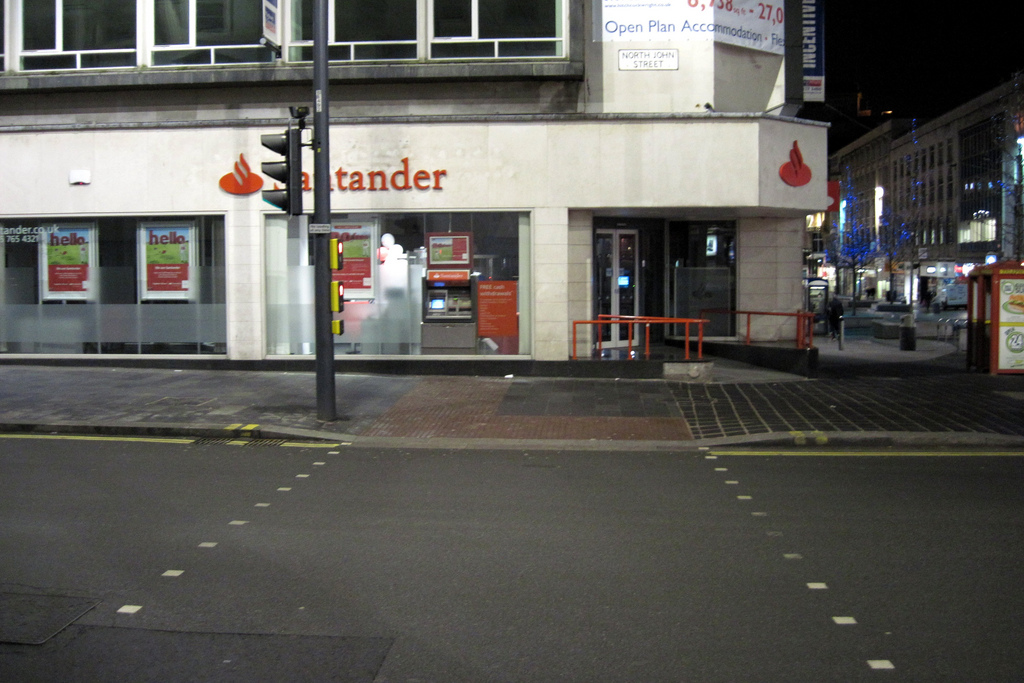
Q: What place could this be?
A: It is a store.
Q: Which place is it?
A: It is a store.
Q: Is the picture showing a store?
A: Yes, it is showing a store.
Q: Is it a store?
A: Yes, it is a store.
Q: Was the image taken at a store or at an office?
A: It was taken at a store.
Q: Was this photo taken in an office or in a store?
A: It was taken at a store.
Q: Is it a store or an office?
A: It is a store.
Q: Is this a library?
A: No, it is a store.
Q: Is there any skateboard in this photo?
A: No, there are no skateboards.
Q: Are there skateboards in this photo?
A: No, there are no skateboards.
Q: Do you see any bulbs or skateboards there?
A: No, there are no skateboards or bulbs.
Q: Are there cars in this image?
A: No, there are no cars.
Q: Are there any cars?
A: No, there are no cars.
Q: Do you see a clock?
A: No, there are no clocks.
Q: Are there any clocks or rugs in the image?
A: No, there are no clocks or rugs.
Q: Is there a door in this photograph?
A: Yes, there are doors.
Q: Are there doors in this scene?
A: Yes, there are doors.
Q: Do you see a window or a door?
A: Yes, there are doors.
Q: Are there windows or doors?
A: Yes, there are doors.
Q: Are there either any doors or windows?
A: Yes, there are doors.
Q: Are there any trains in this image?
A: No, there are no trains.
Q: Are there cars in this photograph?
A: No, there are no cars.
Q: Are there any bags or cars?
A: No, there are no cars or bags.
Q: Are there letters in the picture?
A: Yes, there are letters.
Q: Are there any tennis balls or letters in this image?
A: Yes, there are letters.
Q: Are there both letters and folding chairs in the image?
A: No, there are letters but no folding chairs.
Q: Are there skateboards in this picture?
A: No, there are no skateboards.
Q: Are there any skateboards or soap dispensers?
A: No, there are no skateboards or soap dispensers.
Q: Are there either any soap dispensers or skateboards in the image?
A: No, there are no skateboards or soap dispensers.